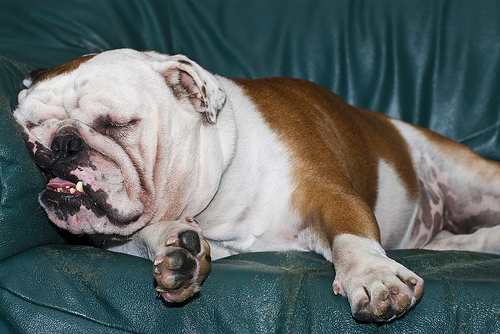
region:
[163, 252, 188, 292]
edge of a paw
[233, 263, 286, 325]
part of a cahir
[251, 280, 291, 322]
part of a chair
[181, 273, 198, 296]
edge of a paw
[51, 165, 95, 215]
part of a mouth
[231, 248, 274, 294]
part of a chair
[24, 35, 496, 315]
white and brown dog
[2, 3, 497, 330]
dog sleep on green couch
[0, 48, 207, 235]
dog face laying on couch arm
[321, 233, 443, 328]
dog white leg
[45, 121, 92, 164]
small dog black nose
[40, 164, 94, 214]
dog tongue and teeth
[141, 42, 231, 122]
dog white hair with brown spots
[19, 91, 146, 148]
dog eyes closed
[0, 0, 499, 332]
dog sleep on leather couch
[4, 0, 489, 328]
dog sleep on green leather couch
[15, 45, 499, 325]
dog that is sleeping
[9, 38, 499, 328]
dog laying on the couch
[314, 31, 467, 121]
wrinkles in the fabric of the couch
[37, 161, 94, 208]
mouth is open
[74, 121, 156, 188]
wrinkles on the face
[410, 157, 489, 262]
gray spots on the body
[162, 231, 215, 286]
black on the bottom of the paw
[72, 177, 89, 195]
tooth sticking out of the mouth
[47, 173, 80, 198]
pink tongue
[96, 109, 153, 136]
eye is closed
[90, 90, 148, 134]
dog has it's eyes closed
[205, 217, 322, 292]
dog is lying on furniture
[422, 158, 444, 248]
dog has spots on the belly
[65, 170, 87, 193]
dog's teeth are showing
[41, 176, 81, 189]
dog's tongue is sticking out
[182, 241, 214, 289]
pad of the dog's paw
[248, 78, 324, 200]
dog is brown and white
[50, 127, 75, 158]
dog's nose is black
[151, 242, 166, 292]
dog's toe nails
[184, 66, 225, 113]
brown spots on his ear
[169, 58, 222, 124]
The right ear of the dog.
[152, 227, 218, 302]
The front left paw of the dog.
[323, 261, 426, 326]
The front right paw of the dog.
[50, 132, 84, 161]
The nose of the dog.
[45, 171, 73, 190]
The tongue of the dog.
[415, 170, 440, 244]
The spots on the dog's stomach.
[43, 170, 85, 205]
The mouth of the dog.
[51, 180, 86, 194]
The teeth of the dog.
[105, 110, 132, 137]
The right eye of the dog.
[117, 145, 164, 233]
The wrinkles on the right side of the dog's face.